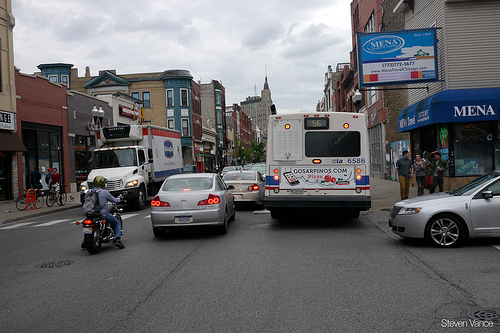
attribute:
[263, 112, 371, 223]
white bus — in the picture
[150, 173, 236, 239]
silver car — Silver 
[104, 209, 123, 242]
pants — blue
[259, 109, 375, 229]
bus — White 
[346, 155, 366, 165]
numbers — Blue 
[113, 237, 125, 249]
black shoe — black 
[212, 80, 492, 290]
bus — white 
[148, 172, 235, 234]
car — Silver 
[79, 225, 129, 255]
shoes — black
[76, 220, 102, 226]
tail light — Red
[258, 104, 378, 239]
bus — white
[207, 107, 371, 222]
bus — white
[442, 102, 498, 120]
letters — White 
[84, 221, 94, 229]
taillight — Red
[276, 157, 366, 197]
letters — Blue 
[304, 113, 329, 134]
numbers — Green 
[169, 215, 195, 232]
plate — White 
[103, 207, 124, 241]
jeans — blue